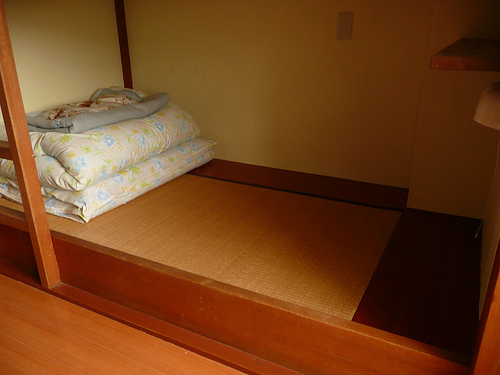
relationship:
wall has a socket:
[122, 3, 492, 228] [338, 11, 353, 41]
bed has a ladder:
[2, 158, 499, 371] [1, 10, 63, 291]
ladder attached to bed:
[1, 10, 63, 291] [2, 158, 499, 371]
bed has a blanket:
[2, 158, 499, 371] [20, 85, 171, 135]